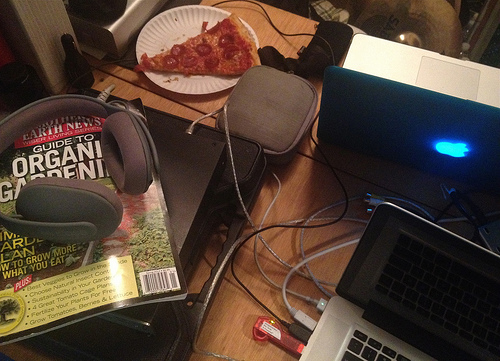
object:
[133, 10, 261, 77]
pizza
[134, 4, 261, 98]
plate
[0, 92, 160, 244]
head phone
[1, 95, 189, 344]
magazine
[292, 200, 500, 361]
laptop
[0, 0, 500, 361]
desk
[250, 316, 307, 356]
flash drive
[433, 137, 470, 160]
logo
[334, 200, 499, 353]
monitor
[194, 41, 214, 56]
pepperoni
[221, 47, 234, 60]
pepperoni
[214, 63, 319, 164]
compact disc wallet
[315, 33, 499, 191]
laptop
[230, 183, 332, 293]
cable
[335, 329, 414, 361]
keyboard